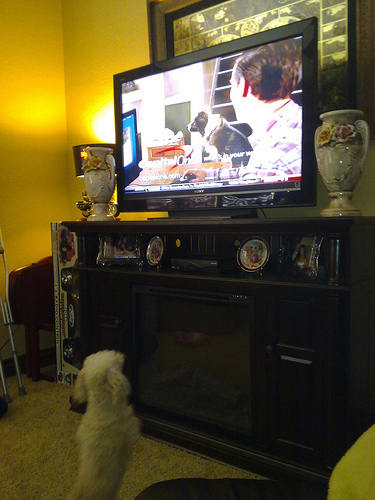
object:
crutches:
[0, 230, 28, 399]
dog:
[71, 349, 143, 500]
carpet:
[0, 359, 279, 500]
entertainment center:
[57, 216, 375, 500]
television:
[111, 14, 319, 220]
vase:
[83, 146, 117, 223]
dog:
[186, 109, 253, 168]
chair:
[7, 253, 70, 385]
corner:
[57, 0, 75, 221]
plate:
[236, 235, 271, 273]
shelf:
[237, 235, 264, 281]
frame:
[274, 234, 323, 281]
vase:
[313, 108, 370, 218]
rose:
[329, 122, 357, 143]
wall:
[0, 0, 167, 360]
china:
[146, 235, 165, 267]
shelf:
[138, 232, 169, 273]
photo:
[103, 233, 141, 259]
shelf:
[73, 264, 351, 300]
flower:
[85, 154, 103, 172]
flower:
[318, 127, 336, 147]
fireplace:
[130, 283, 258, 450]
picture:
[146, 0, 375, 141]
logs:
[192, 364, 245, 408]